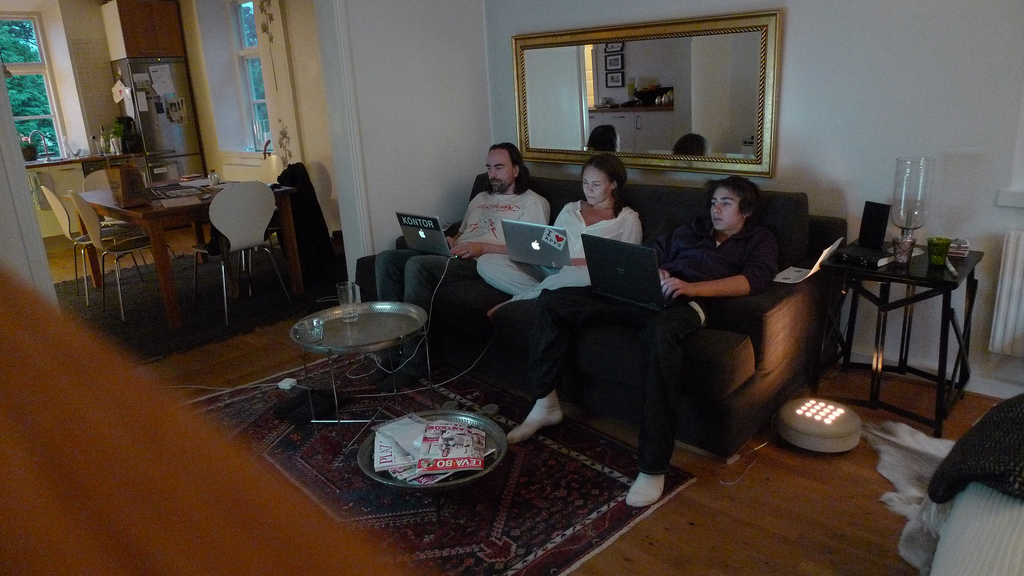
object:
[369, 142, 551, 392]
man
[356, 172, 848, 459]
couch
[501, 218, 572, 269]
laptop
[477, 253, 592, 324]
lap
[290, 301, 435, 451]
table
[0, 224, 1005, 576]
floor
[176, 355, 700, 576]
rug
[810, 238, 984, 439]
table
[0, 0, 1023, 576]
room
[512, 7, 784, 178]
frame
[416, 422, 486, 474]
magazine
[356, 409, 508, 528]
table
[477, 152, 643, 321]
person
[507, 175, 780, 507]
person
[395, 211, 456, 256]
laptop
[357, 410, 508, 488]
tray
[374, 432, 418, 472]
magazine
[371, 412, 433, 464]
magazine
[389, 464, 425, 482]
magazine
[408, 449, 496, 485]
magazine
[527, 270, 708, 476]
pants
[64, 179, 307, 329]
table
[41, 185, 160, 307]
chair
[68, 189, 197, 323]
chair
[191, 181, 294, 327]
chair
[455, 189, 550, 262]
shirt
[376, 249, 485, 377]
jeans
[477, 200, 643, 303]
clothing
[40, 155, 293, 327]
chairs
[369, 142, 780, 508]
people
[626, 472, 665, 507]
sock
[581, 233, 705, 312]
computer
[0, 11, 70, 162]
window